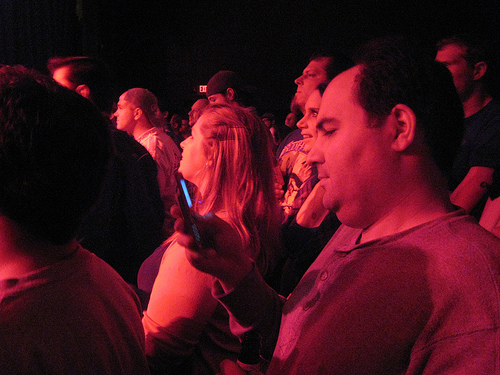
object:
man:
[174, 47, 499, 374]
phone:
[174, 173, 206, 247]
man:
[202, 69, 271, 141]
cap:
[204, 68, 258, 108]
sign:
[197, 84, 207, 92]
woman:
[132, 107, 277, 375]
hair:
[197, 104, 281, 259]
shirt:
[225, 216, 499, 373]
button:
[319, 271, 328, 281]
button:
[335, 246, 349, 258]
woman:
[286, 77, 353, 250]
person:
[429, 38, 499, 224]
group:
[0, 35, 499, 375]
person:
[103, 81, 182, 214]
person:
[48, 57, 105, 129]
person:
[186, 97, 210, 126]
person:
[0, 66, 149, 375]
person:
[289, 56, 352, 141]